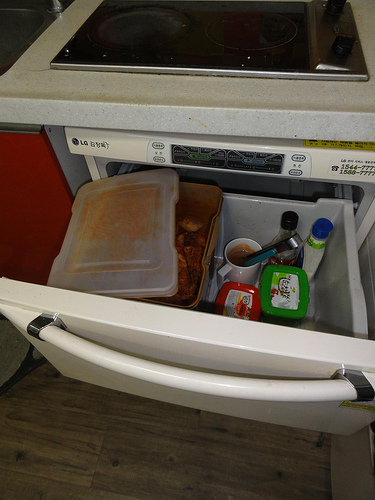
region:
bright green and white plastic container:
[260, 263, 310, 317]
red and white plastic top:
[216, 282, 257, 318]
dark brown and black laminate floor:
[2, 436, 344, 494]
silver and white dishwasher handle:
[12, 312, 371, 399]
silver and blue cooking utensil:
[244, 235, 301, 265]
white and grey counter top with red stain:
[8, 77, 368, 130]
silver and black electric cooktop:
[48, 3, 369, 81]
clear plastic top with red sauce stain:
[49, 168, 177, 294]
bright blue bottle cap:
[311, 213, 333, 239]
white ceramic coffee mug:
[219, 236, 259, 283]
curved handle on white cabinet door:
[4, 278, 367, 435]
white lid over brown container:
[63, 170, 217, 294]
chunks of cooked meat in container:
[169, 187, 199, 292]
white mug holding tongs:
[215, 226, 297, 273]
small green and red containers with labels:
[214, 260, 311, 312]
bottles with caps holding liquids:
[270, 210, 330, 271]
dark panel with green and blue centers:
[165, 136, 285, 168]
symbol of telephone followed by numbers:
[323, 150, 368, 169]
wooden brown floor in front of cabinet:
[18, 435, 292, 490]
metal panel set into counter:
[47, 2, 369, 117]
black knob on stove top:
[330, 33, 355, 56]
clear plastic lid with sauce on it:
[44, 166, 179, 298]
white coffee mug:
[216, 236, 259, 286]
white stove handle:
[2, 306, 370, 408]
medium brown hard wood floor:
[3, 358, 330, 494]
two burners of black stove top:
[51, 2, 310, 76]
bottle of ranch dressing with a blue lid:
[298, 217, 333, 283]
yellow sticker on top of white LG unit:
[302, 138, 373, 151]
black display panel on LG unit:
[172, 145, 283, 172]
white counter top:
[2, 1, 372, 142]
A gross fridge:
[6, 73, 369, 438]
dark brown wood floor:
[14, 382, 249, 491]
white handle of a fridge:
[41, 298, 366, 429]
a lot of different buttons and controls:
[146, 139, 313, 186]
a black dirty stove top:
[47, 1, 356, 66]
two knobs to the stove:
[323, 0, 364, 60]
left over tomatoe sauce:
[47, 175, 244, 338]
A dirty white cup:
[220, 229, 299, 288]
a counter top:
[20, 56, 370, 137]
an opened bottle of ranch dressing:
[294, 213, 341, 275]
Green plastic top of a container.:
[259, 262, 311, 319]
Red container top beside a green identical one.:
[217, 279, 260, 320]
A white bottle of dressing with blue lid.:
[296, 216, 335, 281]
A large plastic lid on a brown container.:
[44, 166, 178, 299]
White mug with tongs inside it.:
[214, 238, 263, 288]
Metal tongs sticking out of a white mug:
[245, 233, 303, 263]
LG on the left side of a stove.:
[77, 137, 88, 147]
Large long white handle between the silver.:
[37, 324, 357, 397]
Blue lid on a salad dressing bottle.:
[310, 215, 332, 239]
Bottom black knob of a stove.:
[330, 30, 358, 58]